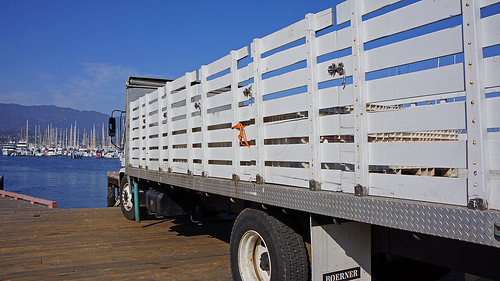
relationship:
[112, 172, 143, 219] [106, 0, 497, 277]
tire in truck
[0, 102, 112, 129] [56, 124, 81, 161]
mountain range behind docked boat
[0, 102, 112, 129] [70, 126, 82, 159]
mountain range behind boat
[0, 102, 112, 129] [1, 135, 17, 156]
mountain range behind boats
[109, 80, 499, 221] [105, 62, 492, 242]
planks on truck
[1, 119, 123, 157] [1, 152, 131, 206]
yachts in ocean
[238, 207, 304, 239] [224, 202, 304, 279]
edge of wheel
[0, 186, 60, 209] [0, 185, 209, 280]
red rail on pier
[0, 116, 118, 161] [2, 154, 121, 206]
boats docked in water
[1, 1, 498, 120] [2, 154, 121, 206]
sky above water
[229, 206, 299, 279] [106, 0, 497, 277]
back wheel on truck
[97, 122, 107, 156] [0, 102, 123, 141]
boat near mountain range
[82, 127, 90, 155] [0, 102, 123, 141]
boat near mountain range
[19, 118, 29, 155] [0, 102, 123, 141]
boat near mountain range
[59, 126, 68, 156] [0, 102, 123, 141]
boat near mountain range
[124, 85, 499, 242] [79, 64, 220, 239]
flat bed on truck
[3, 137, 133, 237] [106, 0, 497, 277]
dock near truck